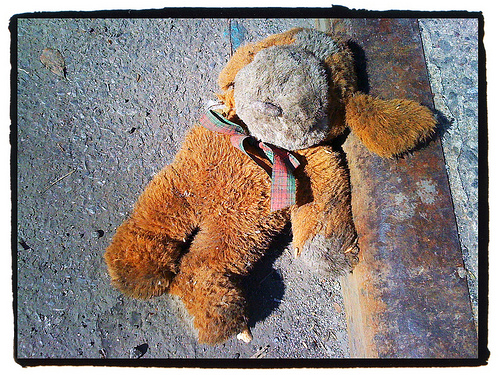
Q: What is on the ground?
A: A stuffed animal.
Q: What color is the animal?
A: Brown.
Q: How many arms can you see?
A: One.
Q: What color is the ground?
A: Gray.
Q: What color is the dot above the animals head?
A: Blue.